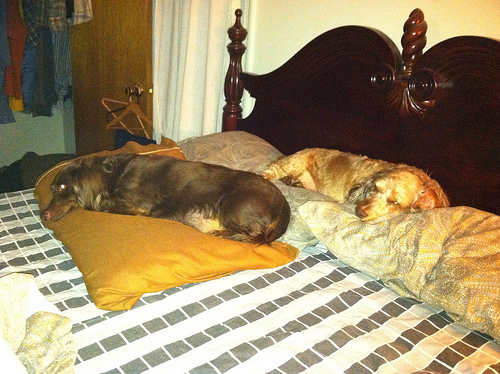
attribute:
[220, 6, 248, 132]
bedpost — dark brown, polished, wooden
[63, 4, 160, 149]
door — brown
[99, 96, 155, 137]
hangers — wooden, plastic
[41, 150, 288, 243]
dog — black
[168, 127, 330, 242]
pillow case — paisley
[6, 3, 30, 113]
clothes — red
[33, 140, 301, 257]
dog — sleeping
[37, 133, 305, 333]
pillow — orange, big, yellow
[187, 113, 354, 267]
pillow — yellow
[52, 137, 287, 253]
dog — dark brown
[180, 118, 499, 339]
pillow — big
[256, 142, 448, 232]
dog — big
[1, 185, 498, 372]
bedspread — white, black, striped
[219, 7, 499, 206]
headboard — deep auburn, wooden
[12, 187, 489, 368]
bed — wooden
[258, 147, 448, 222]
dog — sleeping, brown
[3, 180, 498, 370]
comforter — black, white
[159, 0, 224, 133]
curtains — white, fabric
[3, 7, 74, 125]
clothing — hanging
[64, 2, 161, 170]
door — closed, wood